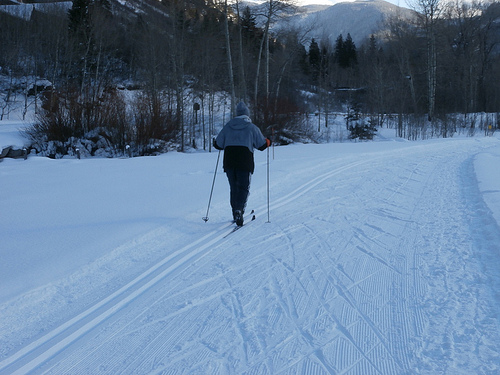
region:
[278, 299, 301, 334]
part of a floor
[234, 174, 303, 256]
part of a hooker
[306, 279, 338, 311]
part fo a snow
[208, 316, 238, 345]
part of a snow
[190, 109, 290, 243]
person standing on the snow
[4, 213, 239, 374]
tracks from the skis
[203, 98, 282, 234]
person skiing on the snow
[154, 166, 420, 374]
several tracks in the snow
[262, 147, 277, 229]
long and thin ski pole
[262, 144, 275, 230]
ski pole sticking in the snow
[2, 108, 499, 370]
ground is covered in white snow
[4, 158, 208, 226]
patch of snow that is perfectly smooth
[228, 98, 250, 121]
back of someone's head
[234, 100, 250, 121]
hat on the head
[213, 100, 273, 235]
this is a man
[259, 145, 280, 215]
this is a stick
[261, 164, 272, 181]
the stick is white in color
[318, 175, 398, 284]
this is the snow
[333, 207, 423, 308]
the snow is white in color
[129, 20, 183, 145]
this is a tree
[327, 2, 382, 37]
this is a mountain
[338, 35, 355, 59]
the leaves are green in color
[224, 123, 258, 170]
this is a jacket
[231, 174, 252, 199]
this is a trouser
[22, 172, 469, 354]
Ground is white color.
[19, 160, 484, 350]
Snow is in ground.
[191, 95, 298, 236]
One man is skiing in snow.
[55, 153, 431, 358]
Marks are seen in snow.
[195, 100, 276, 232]
Man is holding ski poles in hand.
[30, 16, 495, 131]
trees are in front of man.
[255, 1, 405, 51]
Hills are behind the trees.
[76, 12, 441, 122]
Trees are without leaves.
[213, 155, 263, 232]
Man is wearing black pant.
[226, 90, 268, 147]
Man is wearing grey cap.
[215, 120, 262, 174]
The jacket the skier is wearing.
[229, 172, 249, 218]
The pants the skier is wearing.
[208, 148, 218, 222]
The left ski pole.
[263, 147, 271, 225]
The right ski pole.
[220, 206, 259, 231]
The skis the person is standing on.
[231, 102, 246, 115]
The hat the person is wearing.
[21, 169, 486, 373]
The tracks on the snow.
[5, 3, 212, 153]
The trees on the left.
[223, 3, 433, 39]
The mountain in the distance.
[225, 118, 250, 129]
The hood of the jacket.